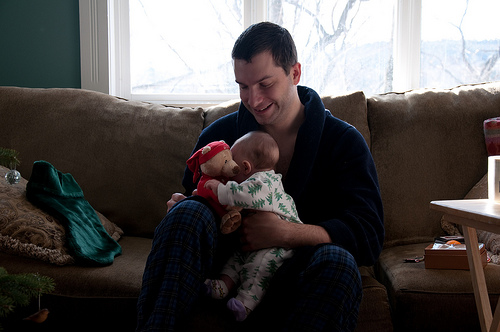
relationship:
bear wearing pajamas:
[190, 133, 243, 231] [181, 136, 230, 199]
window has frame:
[127, 0, 498, 94] [80, 0, 420, 111]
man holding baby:
[131, 18, 393, 330] [200, 127, 306, 317]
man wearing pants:
[131, 18, 393, 330] [145, 193, 366, 330]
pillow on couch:
[0, 179, 126, 266] [2, 82, 498, 329]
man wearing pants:
[131, 18, 393, 330] [125, 199, 360, 330]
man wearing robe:
[131, 18, 393, 330] [127, 80, 395, 330]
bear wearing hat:
[190, 133, 243, 231] [181, 136, 231, 176]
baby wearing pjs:
[200, 127, 306, 317] [206, 167, 303, 312]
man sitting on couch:
[131, 18, 393, 330] [2, 82, 498, 329]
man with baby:
[131, 18, 393, 330] [213, 109, 324, 262]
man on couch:
[131, 18, 393, 330] [14, 77, 498, 277]